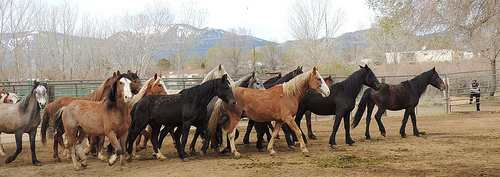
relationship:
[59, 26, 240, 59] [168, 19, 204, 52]
hills have snow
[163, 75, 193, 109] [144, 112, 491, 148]
snow on ground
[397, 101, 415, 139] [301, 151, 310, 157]
leg of hoof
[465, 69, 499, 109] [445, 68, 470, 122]
person by fence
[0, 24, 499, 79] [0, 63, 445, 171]
hills behind group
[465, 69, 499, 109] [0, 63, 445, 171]
person watching group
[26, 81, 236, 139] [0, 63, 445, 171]
group of group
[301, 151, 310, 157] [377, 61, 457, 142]
hoof in front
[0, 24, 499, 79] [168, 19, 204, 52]
hills with snow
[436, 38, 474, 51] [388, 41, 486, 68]
roof of building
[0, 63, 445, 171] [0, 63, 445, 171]
group of group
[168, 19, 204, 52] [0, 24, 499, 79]
snow on hills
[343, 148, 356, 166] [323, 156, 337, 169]
patch of green